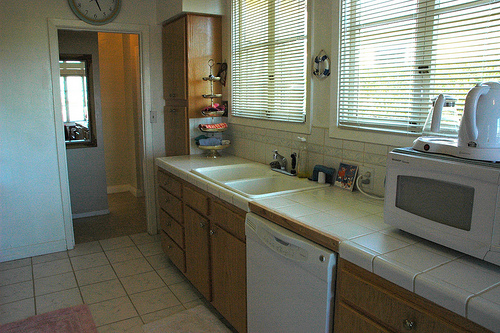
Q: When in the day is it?
A: Daytime.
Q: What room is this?
A: Kitchen.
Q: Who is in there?
A: No one.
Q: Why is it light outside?
A: Daytime.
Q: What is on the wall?
A: Clock.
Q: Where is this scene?
A: Inside a house.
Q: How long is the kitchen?
A: Pretty long.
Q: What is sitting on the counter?
A: Microwave.